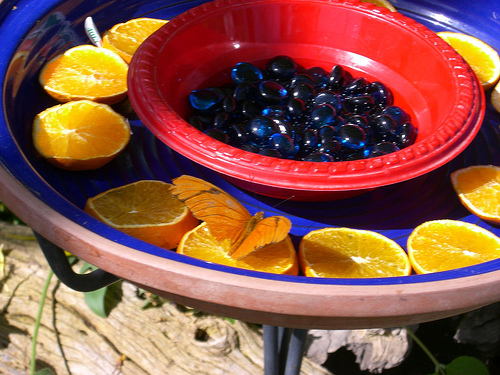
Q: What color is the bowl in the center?
A: Red.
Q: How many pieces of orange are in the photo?
A: Eleven.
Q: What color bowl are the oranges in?
A: Blue.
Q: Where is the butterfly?
A: On one of the orange slices.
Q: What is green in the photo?
A: Plants.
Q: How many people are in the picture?
A: None.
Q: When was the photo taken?
A: During the day.